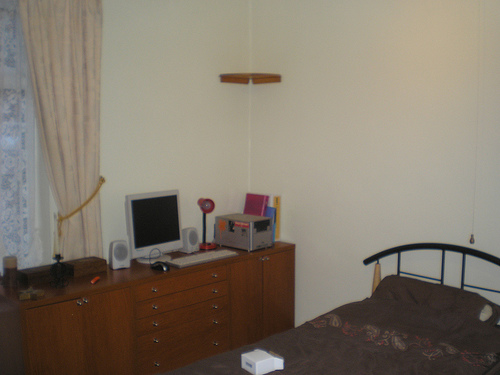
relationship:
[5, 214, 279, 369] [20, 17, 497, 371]
dresser in bedroom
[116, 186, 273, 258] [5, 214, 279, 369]
computer on dresser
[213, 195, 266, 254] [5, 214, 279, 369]
cassette player on dresser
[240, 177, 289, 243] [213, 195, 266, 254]
books behind cassette player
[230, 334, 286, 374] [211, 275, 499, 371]
box on bed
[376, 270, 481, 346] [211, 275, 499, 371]
pillow on bed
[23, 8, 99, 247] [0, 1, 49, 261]
curtains near window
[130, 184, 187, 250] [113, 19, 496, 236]
monitor near wall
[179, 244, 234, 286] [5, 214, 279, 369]
keyboard on dresser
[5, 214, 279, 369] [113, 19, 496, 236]
dresser near wall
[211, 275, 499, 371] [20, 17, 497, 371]
bed in bedroom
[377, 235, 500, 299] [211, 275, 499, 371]
headboard on bed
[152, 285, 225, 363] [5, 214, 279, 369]
knobs on dresser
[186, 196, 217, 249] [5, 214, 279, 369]
light on dresser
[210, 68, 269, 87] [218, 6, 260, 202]
shelf in corner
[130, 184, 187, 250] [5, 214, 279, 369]
monitor on dresser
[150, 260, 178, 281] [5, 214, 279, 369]
mouse on dresser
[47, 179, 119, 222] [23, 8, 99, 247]
cord on curtains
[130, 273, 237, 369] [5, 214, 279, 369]
drawers on dresser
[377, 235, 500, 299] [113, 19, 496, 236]
headboard near wall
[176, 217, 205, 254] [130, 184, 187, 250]
speaker beside monitor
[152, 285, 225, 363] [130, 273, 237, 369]
knobs on drawers